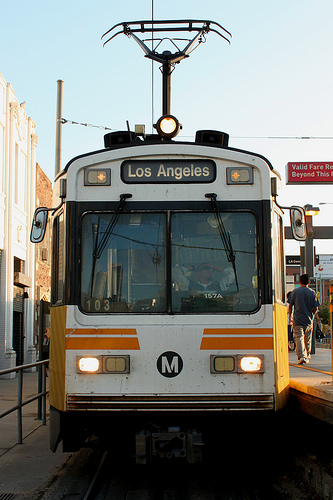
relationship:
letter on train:
[156, 352, 185, 379] [29, 112, 307, 472]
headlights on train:
[76, 354, 265, 376] [29, 112, 307, 472]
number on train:
[201, 292, 226, 298] [29, 112, 307, 472]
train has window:
[29, 112, 307, 472] [275, 214, 284, 301]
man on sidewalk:
[285, 275, 320, 367] [286, 330, 331, 429]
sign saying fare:
[286, 160, 331, 185] [308, 164, 322, 171]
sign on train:
[126, 160, 213, 183] [29, 112, 307, 472]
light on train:
[82, 170, 112, 184] [29, 112, 307, 472]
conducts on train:
[102, 18, 232, 65] [29, 112, 307, 472]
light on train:
[157, 114, 178, 137] [32, 131, 310, 467]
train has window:
[32, 131, 310, 467] [80, 207, 264, 317]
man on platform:
[285, 275, 320, 367] [284, 345, 331, 402]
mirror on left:
[31, 206, 49, 243] [7, 172, 70, 403]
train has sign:
[32, 131, 310, 467] [126, 160, 213, 183]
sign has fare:
[286, 160, 331, 185] [308, 164, 322, 171]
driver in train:
[170, 261, 236, 313] [32, 131, 310, 467]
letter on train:
[156, 352, 185, 379] [32, 131, 310, 467]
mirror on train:
[31, 206, 49, 243] [32, 131, 310, 467]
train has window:
[32, 131, 310, 467] [275, 214, 284, 301]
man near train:
[286, 273, 321, 366] [32, 131, 310, 467]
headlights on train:
[76, 354, 265, 376] [32, 131, 310, 467]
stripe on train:
[61, 325, 141, 352] [32, 131, 310, 467]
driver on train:
[170, 261, 236, 313] [32, 131, 310, 467]